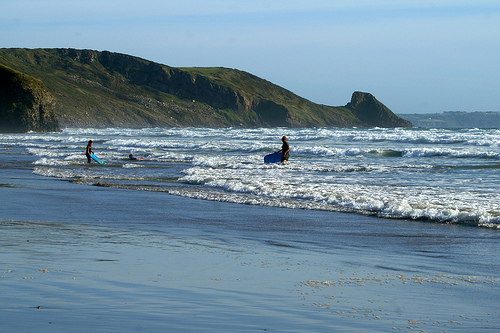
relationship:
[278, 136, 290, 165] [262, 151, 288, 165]
man with board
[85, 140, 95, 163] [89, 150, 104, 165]
man with boogie board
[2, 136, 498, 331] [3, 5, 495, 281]
beach in inlet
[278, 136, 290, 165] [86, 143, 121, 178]
man holding board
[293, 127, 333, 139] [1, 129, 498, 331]
tides in ocean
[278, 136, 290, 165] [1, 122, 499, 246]
man in water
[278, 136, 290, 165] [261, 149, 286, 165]
man holding surfboard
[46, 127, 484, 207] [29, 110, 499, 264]
waves across water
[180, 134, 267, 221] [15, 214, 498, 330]
foam bubbles on sand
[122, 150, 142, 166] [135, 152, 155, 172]
person wears red trunks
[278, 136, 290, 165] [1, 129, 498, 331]
man in ocean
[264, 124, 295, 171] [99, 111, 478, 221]
man in ocean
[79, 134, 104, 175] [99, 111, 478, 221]
man in ocean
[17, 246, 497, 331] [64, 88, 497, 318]
shore front ocean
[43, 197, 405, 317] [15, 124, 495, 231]
water in beach